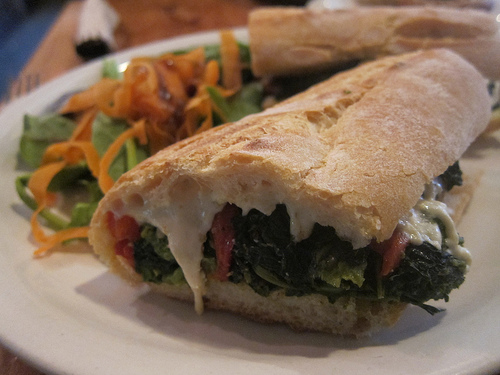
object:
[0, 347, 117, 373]
edge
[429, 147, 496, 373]
side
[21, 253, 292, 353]
inside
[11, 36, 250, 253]
section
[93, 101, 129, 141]
vegetables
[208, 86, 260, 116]
vegetable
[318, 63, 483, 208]
section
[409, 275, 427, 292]
part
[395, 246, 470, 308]
vegetable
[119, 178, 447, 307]
sauce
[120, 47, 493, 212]
piece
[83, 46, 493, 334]
bread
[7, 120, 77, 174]
spinach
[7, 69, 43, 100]
fork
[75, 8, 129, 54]
napkin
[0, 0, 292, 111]
table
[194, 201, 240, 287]
tomato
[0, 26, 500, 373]
plate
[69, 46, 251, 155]
cheese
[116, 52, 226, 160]
carrots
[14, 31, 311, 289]
salad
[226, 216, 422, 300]
broccoli